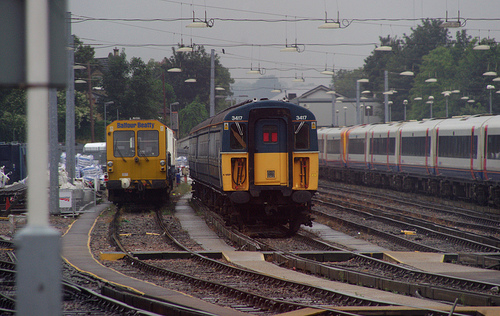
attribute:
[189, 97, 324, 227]
train — blue, yellow, coming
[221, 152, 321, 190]
trim — yellow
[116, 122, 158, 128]
writing — blue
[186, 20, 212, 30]
lights — hanging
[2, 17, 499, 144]
trees — green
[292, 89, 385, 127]
house — white, giant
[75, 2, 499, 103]
sky — hazy